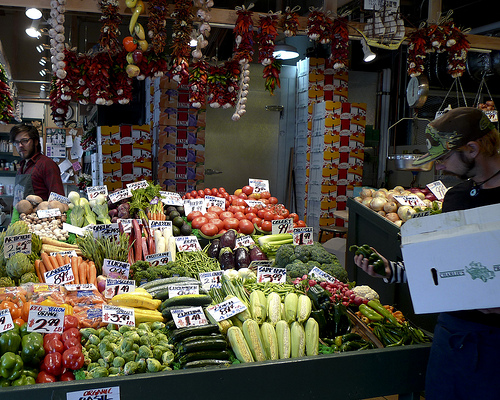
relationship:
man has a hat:
[10, 123, 64, 219] [409, 108, 492, 165]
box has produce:
[344, 197, 438, 336] [355, 185, 445, 228]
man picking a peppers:
[10, 123, 64, 219] [62, 329, 82, 349]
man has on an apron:
[10, 123, 64, 219] [7, 167, 34, 227]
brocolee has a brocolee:
[271, 247, 298, 266] [273, 242, 296, 268]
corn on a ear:
[297, 291, 311, 322] [260, 292, 266, 323]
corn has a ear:
[297, 291, 311, 322] [260, 292, 266, 323]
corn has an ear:
[297, 291, 311, 322] [260, 292, 266, 323]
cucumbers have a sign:
[171, 324, 219, 344] [170, 305, 210, 328]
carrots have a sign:
[36, 250, 97, 288] [45, 264, 75, 286]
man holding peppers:
[10, 123, 64, 219] [348, 242, 386, 275]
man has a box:
[355, 108, 495, 399] [401, 205, 498, 314]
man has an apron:
[10, 123, 64, 219] [7, 167, 34, 227]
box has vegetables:
[401, 205, 498, 314] [354, 184, 444, 227]